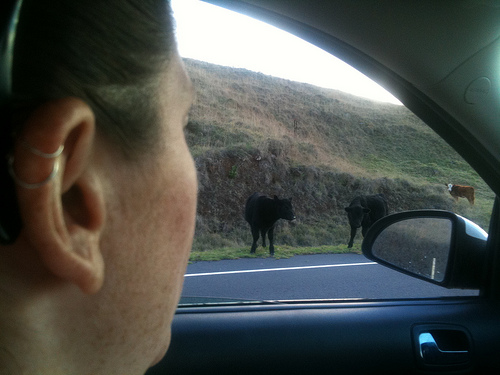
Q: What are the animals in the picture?
A: Cows.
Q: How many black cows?
A: Two.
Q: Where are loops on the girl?
A: The ear.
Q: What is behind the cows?
A: A grassy hill.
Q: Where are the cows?
A: Across a street.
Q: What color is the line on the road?
A: White.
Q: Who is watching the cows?
A: A lady.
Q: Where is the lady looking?
A: To the left.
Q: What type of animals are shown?
A: Cows.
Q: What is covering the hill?
A: Dead grass.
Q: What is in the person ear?
A: Earrings.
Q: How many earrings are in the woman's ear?
A: Two.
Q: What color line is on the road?
A: White.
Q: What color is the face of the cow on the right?
A: White.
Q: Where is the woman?
A: Inside car.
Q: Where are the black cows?
A: Beside the road.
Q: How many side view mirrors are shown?
A: One.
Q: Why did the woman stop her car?
A: To look at the animals.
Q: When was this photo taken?
A: Day time.